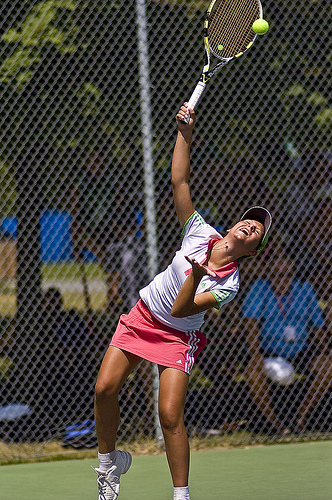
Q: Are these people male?
A: No, they are both male and female.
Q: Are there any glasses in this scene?
A: No, there are no glasses.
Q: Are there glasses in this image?
A: No, there are no glasses.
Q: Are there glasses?
A: No, there are no glasses.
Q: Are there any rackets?
A: Yes, there is a racket.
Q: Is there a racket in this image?
A: Yes, there is a racket.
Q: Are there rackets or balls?
A: Yes, there is a racket.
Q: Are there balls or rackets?
A: Yes, there is a racket.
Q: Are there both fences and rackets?
A: Yes, there are both a racket and a fence.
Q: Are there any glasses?
A: No, there are no glasses.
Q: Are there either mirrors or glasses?
A: No, there are no glasses or mirrors.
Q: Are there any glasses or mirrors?
A: No, there are no glasses or mirrors.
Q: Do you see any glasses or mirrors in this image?
A: No, there are no glasses or mirrors.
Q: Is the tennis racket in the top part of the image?
A: Yes, the tennis racket is in the top of the image.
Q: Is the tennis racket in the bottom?
A: No, the tennis racket is in the top of the image.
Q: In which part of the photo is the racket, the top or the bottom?
A: The racket is in the top of the image.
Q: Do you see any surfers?
A: No, there are no surfers.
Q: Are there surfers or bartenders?
A: No, there are no surfers or bartenders.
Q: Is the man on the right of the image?
A: Yes, the man is on the right of the image.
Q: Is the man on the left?
A: No, the man is on the right of the image.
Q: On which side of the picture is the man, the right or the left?
A: The man is on the right of the image.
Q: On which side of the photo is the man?
A: The man is on the right of the image.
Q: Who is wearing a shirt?
A: The man is wearing a shirt.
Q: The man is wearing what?
A: The man is wearing a shirt.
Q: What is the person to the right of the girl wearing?
A: The man is wearing a shirt.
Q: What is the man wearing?
A: The man is wearing a shirt.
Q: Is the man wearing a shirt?
A: Yes, the man is wearing a shirt.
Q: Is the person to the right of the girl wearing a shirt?
A: Yes, the man is wearing a shirt.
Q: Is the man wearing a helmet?
A: No, the man is wearing a shirt.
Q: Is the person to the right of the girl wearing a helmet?
A: No, the man is wearing a shirt.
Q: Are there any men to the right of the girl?
A: Yes, there is a man to the right of the girl.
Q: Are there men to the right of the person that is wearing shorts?
A: Yes, there is a man to the right of the girl.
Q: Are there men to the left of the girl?
A: No, the man is to the right of the girl.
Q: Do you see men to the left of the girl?
A: No, the man is to the right of the girl.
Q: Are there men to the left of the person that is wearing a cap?
A: No, the man is to the right of the girl.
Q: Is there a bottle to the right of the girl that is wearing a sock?
A: No, there is a man to the right of the girl.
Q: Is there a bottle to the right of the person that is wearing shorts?
A: No, there is a man to the right of the girl.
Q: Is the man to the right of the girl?
A: Yes, the man is to the right of the girl.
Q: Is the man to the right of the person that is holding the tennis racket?
A: Yes, the man is to the right of the girl.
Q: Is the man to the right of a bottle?
A: No, the man is to the right of the girl.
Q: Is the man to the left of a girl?
A: No, the man is to the right of a girl.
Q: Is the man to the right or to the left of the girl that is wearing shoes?
A: The man is to the right of the girl.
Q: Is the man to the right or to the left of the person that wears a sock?
A: The man is to the right of the girl.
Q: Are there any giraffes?
A: No, there are no giraffes.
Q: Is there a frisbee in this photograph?
A: No, there are no frisbees.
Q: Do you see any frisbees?
A: No, there are no frisbees.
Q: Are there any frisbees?
A: No, there are no frisbees.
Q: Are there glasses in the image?
A: No, there are no glasses.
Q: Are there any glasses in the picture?
A: No, there are no glasses.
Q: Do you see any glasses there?
A: No, there are no glasses.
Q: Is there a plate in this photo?
A: No, there are no plates.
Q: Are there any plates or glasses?
A: No, there are no plates or glasses.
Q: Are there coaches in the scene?
A: No, there are no coaches.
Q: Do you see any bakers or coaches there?
A: No, there are no coaches or bakers.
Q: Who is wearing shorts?
A: The girl is wearing shorts.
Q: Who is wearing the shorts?
A: The girl is wearing shorts.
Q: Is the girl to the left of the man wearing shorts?
A: Yes, the girl is wearing shorts.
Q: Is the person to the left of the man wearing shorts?
A: Yes, the girl is wearing shorts.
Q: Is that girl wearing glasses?
A: No, the girl is wearing shorts.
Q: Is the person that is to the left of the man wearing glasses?
A: No, the girl is wearing shorts.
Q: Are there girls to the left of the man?
A: Yes, there is a girl to the left of the man.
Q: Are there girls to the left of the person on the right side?
A: Yes, there is a girl to the left of the man.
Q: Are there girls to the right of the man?
A: No, the girl is to the left of the man.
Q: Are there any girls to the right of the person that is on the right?
A: No, the girl is to the left of the man.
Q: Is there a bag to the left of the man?
A: No, there is a girl to the left of the man.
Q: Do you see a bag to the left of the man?
A: No, there is a girl to the left of the man.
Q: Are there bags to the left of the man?
A: No, there is a girl to the left of the man.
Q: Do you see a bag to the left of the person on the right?
A: No, there is a girl to the left of the man.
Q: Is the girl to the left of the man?
A: Yes, the girl is to the left of the man.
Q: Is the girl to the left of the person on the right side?
A: Yes, the girl is to the left of the man.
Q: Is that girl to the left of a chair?
A: No, the girl is to the left of the man.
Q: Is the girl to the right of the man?
A: No, the girl is to the left of the man.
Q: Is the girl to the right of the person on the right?
A: No, the girl is to the left of the man.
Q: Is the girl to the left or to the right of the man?
A: The girl is to the left of the man.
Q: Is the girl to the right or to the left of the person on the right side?
A: The girl is to the left of the man.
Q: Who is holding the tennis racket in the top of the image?
A: The girl is holding the racket.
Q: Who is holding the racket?
A: The girl is holding the racket.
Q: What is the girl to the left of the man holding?
A: The girl is holding the racket.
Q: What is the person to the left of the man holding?
A: The girl is holding the racket.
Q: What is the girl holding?
A: The girl is holding the racket.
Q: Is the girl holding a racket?
A: Yes, the girl is holding a racket.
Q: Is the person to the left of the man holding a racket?
A: Yes, the girl is holding a racket.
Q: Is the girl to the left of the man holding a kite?
A: No, the girl is holding a racket.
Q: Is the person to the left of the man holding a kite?
A: No, the girl is holding a racket.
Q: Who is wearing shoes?
A: The girl is wearing shoes.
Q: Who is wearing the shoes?
A: The girl is wearing shoes.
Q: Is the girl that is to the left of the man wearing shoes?
A: Yes, the girl is wearing shoes.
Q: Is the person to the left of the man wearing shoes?
A: Yes, the girl is wearing shoes.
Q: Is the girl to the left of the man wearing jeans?
A: No, the girl is wearing shoes.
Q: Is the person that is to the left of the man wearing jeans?
A: No, the girl is wearing shoes.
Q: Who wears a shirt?
A: The girl wears a shirt.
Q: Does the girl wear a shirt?
A: Yes, the girl wears a shirt.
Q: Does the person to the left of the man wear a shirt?
A: Yes, the girl wears a shirt.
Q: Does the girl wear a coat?
A: No, the girl wears a shirt.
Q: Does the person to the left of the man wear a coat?
A: No, the girl wears a shirt.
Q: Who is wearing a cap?
A: The girl is wearing a cap.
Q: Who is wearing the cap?
A: The girl is wearing a cap.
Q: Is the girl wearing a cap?
A: Yes, the girl is wearing a cap.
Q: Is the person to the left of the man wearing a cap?
A: Yes, the girl is wearing a cap.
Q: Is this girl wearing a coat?
A: No, the girl is wearing a cap.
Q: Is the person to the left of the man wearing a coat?
A: No, the girl is wearing a cap.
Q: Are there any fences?
A: Yes, there is a fence.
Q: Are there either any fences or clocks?
A: Yes, there is a fence.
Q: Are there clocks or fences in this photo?
A: Yes, there is a fence.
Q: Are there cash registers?
A: No, there are no cash registers.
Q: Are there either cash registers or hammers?
A: No, there are no cash registers or hammers.